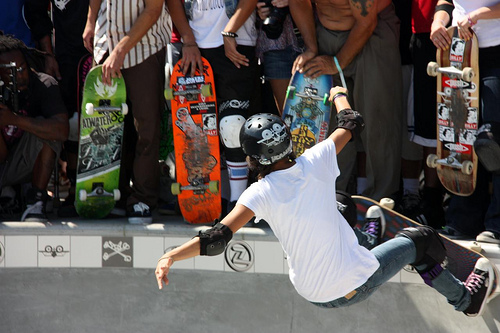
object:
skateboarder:
[155, 78, 500, 319]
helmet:
[237, 112, 300, 169]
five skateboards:
[74, 64, 130, 220]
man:
[0, 31, 73, 223]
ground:
[3, 210, 499, 333]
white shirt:
[234, 138, 383, 306]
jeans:
[312, 221, 476, 316]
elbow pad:
[197, 223, 240, 258]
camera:
[253, 1, 291, 42]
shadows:
[2, 272, 155, 333]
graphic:
[82, 109, 117, 172]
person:
[247, 2, 303, 115]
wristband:
[329, 90, 349, 103]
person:
[285, 1, 406, 210]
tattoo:
[351, 1, 373, 18]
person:
[428, 0, 499, 242]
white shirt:
[446, 1, 500, 55]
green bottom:
[85, 67, 117, 212]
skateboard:
[170, 52, 228, 227]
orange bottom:
[168, 52, 226, 228]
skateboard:
[278, 54, 336, 161]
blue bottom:
[282, 61, 334, 158]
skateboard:
[427, 22, 483, 195]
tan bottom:
[436, 26, 479, 201]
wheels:
[113, 190, 121, 203]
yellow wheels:
[174, 183, 186, 197]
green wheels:
[301, 85, 305, 96]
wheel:
[378, 195, 397, 212]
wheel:
[464, 240, 480, 252]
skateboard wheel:
[425, 58, 441, 77]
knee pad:
[216, 109, 251, 153]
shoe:
[357, 204, 386, 245]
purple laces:
[363, 218, 381, 234]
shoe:
[459, 255, 493, 317]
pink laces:
[464, 271, 488, 297]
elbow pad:
[335, 108, 373, 136]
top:
[0, 230, 500, 280]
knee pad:
[329, 188, 361, 231]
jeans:
[430, 69, 500, 246]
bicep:
[48, 105, 73, 125]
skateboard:
[341, 191, 500, 308]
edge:
[350, 195, 480, 260]